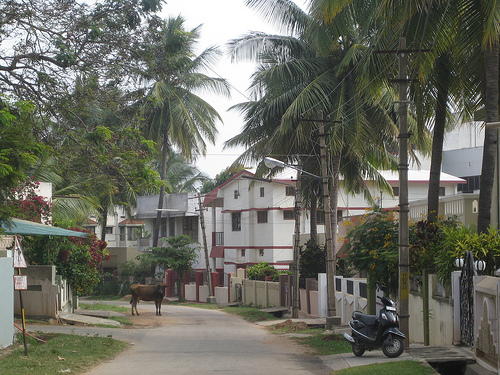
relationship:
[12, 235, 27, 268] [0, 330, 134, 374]
sign in grass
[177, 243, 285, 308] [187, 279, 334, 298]
fence around yard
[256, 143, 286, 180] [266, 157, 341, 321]
light on pole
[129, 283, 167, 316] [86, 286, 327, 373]
cow standing next to road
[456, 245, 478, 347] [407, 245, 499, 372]
gate in wall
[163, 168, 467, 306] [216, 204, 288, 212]
building with trim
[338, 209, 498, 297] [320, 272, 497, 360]
plants next to wall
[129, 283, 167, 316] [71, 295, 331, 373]
cow standing in road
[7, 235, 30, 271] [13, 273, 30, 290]
sign on sign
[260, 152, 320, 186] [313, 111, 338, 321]
street light extending from pole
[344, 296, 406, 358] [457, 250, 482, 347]
bike in front of gate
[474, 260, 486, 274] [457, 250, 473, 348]
light near gate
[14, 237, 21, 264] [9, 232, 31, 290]
person standing on sign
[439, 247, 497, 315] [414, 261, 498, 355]
lamps at gate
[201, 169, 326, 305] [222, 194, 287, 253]
building with red accents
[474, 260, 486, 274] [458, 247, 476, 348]
light on side of gate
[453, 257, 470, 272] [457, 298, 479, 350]
light near gate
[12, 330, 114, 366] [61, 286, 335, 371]
grass near drive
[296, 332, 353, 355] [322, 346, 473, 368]
grass near drive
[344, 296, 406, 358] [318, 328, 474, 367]
bike in driveway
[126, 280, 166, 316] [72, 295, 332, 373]
cow standing beside a street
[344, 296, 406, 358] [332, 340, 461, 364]
bike parked on pad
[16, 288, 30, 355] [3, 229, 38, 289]
pole with sign